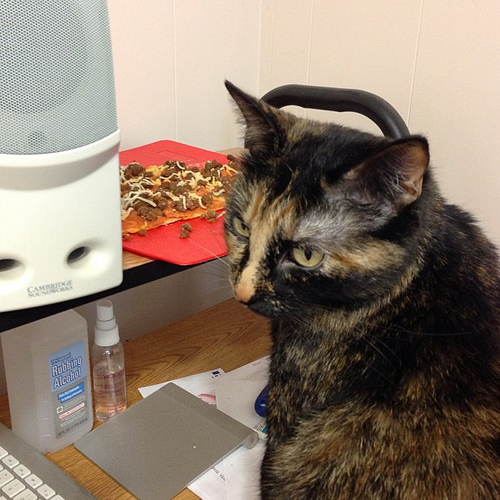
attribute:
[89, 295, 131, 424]
bottle — spray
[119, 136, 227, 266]
plate — red